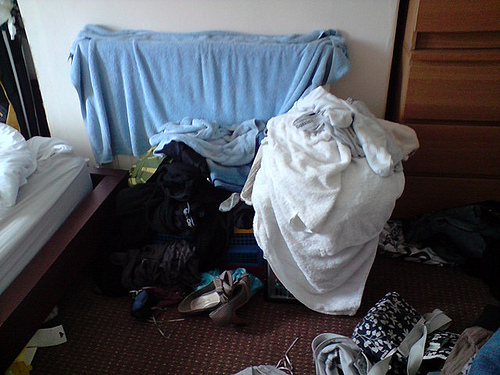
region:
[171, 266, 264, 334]
Shoes on the floor.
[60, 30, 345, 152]
Blanket on the wall.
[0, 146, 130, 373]
Mattress on a bed frame.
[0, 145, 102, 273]
The sheet is white.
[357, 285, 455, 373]
Bag on the floor.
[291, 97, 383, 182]
Underwear in a blanket.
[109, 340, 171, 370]
Dots on the carpet.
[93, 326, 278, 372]
The carpet is maroon.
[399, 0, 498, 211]
The dresser is wooden.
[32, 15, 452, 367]
a dirty room in a home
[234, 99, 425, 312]
a white bag with items in it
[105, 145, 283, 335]
clothes on the floor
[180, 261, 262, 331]
shoes on the ground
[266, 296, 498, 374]
objects piled up on the floor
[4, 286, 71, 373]
items under the bed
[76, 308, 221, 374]
a brown carpet on the floor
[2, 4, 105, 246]
a mattress on a bed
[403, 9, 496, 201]
a dresser drawer in the area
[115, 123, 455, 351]
a floor that is dirty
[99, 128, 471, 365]
a dirty bedroom floor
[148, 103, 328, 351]
a pile of clothes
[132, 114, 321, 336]
clothes piled on the floor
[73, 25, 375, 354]
clothe piles on the floor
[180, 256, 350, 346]
hells on teh floor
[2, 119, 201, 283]
a brown bed frame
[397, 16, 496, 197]
a brown dresser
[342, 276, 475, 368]
a purse on the floor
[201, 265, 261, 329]
these are shoes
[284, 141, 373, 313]
this is a towel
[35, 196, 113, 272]
this is a bed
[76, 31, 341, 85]
this is a towel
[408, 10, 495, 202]
this is a cupbord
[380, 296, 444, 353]
this is a hand bag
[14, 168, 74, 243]
this is a bedsheet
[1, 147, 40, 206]
this is a mosquito net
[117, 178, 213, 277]
these are clothes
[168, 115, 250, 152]
this is a towel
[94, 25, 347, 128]
blue towel draped over rack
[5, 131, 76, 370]
bed on left of room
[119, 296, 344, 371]
red carpet of room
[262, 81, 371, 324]
white towels in bag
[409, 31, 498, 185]
wood cabinet on right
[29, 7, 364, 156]
white wall of bed room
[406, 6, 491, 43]
wooden drawer of cabinet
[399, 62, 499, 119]
wooden drawer of cabinet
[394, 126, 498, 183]
wooden drawer of cabinet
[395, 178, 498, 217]
wooden drawer of cabinet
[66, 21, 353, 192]
blue towel hanging on wall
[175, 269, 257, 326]
pair of shoes next to laundry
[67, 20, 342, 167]
blue towel on white wall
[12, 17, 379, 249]
blue towel on white wall by bed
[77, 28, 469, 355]
mess on floor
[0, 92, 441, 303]
mess on floor by bed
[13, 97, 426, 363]
mess on floor by wood bed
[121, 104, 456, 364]
dirty cloths on floor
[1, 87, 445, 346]
dirty cloths on floor by bed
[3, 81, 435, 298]
dirty cloths on floor by wood bed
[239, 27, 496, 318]
dirty cloths on floor wood dresser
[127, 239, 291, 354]
brown shoes on floor by dirty cloths